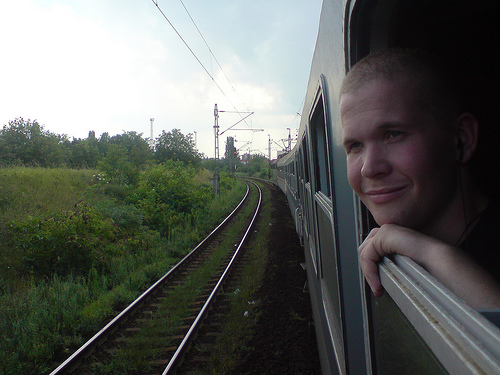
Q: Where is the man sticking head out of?
A: The window.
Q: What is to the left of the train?
A: Train tracks.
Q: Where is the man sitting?
A: Window.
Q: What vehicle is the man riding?
A: Train.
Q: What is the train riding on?
A: Rails.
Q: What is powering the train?
A: Electricity.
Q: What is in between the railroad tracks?
A: Grass.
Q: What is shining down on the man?
A: Sunlight.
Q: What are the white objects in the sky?
A: Clouds.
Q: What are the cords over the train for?
A: Power lines.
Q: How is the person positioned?
A: Sitting.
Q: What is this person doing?
A: Looking out the train window.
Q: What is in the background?
A: Trees.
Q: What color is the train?
A: Green.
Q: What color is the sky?
A: Blue.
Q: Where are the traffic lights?
A: Affixed to the pole.